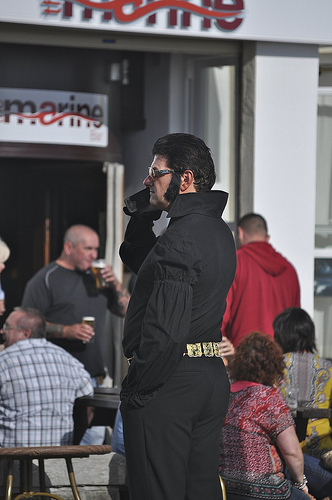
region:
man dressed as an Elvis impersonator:
[107, 129, 240, 493]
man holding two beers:
[30, 216, 118, 340]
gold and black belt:
[125, 333, 228, 376]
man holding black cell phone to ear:
[114, 115, 229, 234]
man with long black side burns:
[140, 123, 223, 214]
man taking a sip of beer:
[44, 216, 124, 302]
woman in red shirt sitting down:
[221, 326, 299, 492]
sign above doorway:
[1, 82, 124, 142]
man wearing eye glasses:
[1, 302, 51, 359]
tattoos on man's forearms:
[112, 276, 136, 321]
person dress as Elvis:
[110, 121, 249, 498]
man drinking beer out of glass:
[46, 215, 122, 354]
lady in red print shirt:
[218, 327, 304, 498]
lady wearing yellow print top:
[269, 307, 330, 402]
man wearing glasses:
[0, 302, 48, 357]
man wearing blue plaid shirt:
[1, 308, 104, 464]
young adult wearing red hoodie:
[230, 207, 315, 361]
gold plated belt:
[133, 332, 244, 381]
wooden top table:
[6, 435, 103, 499]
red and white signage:
[2, 76, 131, 165]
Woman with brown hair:
[234, 329, 326, 484]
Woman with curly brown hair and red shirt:
[224, 330, 309, 490]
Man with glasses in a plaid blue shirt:
[3, 312, 93, 459]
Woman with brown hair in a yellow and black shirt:
[263, 296, 330, 379]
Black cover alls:
[127, 254, 254, 485]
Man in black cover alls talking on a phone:
[125, 137, 255, 304]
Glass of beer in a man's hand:
[87, 259, 138, 317]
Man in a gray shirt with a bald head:
[39, 216, 128, 327]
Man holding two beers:
[17, 218, 174, 358]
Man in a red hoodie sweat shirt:
[225, 209, 313, 349]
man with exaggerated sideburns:
[126, 126, 223, 219]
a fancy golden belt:
[168, 332, 233, 368]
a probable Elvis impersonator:
[113, 131, 232, 498]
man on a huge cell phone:
[107, 129, 223, 235]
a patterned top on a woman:
[224, 380, 293, 499]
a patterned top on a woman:
[278, 353, 328, 445]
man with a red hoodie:
[220, 211, 301, 342]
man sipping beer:
[6, 224, 127, 379]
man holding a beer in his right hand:
[7, 221, 132, 386]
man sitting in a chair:
[0, 305, 118, 448]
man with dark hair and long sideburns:
[90, 110, 245, 470]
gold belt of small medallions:
[124, 322, 224, 370]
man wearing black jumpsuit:
[99, 127, 246, 475]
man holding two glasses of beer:
[11, 199, 125, 365]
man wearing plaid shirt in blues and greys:
[1, 300, 91, 452]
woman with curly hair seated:
[229, 324, 309, 490]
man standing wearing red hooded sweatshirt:
[223, 201, 299, 362]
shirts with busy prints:
[212, 341, 324, 486]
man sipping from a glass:
[48, 220, 117, 298]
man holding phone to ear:
[104, 130, 242, 230]